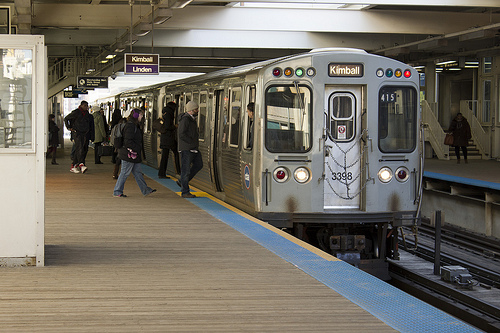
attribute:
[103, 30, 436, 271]
train — engineer, car, station, commuter, boarding, track, passenger, rail, signal, parked, white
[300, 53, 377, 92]
line — route, safety, rail, yellow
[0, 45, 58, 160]
sign — information, location, suspended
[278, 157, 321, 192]
light — service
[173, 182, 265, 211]
rail — transit, between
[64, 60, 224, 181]
transit — mass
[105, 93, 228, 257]
passenger — walking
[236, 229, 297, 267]
edge — blue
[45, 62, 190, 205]
people — walking